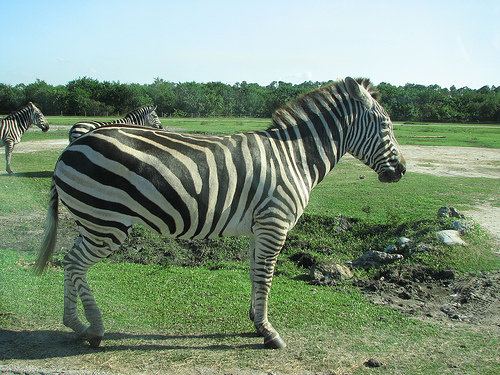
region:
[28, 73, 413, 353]
Zebra on the ground.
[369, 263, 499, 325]
Dirt on the ground.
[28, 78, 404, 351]
black and white stripes on the zebra.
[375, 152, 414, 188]
black nose on the zebra.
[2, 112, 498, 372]
Green grass covering the ground.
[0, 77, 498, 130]
Trees in the background.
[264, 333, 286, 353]
Gay hoof on the zebra.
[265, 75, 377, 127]
Black and white mane on the zebra.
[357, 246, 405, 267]
Rock on the ground.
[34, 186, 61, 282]
White tail on the zebra.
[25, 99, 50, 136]
the head of a zebra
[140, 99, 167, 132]
the head of a zebra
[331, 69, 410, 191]
the head of a zebra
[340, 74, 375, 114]
the ear of a zebra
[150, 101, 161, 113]
the ear of a zebra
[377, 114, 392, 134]
the eye of a zebra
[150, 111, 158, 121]
the eye of a zebra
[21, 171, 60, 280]
the tail of a zebra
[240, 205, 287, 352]
the front leg of a zebra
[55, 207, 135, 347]
the hind legs of a zebra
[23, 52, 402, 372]
Zebra standing in the field.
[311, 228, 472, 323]
Rocks in the field.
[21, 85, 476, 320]
Zebra with black and white stripes.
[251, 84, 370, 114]
The mane of a zebra.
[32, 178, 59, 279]
Tail of a zebra.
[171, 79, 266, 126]
Trees in the distance.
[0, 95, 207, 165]
Two zebras behind the other zebra.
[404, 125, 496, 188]
Dirt in the middle of the field.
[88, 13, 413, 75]
Clear blue sky in the background.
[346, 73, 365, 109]
Ear of a zebra.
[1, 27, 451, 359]
several zebras on a grassland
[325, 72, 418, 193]
the head of a zebra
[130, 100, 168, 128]
the head of a zebra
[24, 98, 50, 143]
the head of a zebra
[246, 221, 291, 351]
the front legs of a zebra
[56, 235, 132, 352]
the rear legs of a zebra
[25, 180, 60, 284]
the tail of a zebra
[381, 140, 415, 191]
the nose of a zebra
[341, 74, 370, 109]
the ear of a zebra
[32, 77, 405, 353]
a zebra in a field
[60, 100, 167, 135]
a zebra in a field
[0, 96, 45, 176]
a zebra in a field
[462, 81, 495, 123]
a tree in the woods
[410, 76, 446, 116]
a tree in the woods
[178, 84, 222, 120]
a tree in the woods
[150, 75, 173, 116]
a tree in the woods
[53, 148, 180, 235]
black stripe on the zebra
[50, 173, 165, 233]
black stripe on the zebra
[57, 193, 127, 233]
black stripe on the zebra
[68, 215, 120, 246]
black stripe on the zebra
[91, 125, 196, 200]
black stripe on the zebra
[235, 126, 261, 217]
black stripe on the zebra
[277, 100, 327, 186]
black stripe on the zebra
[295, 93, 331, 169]
black stripe on the zebra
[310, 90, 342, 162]
black stripe on the zebra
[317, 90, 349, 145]
black stripe on the zebra